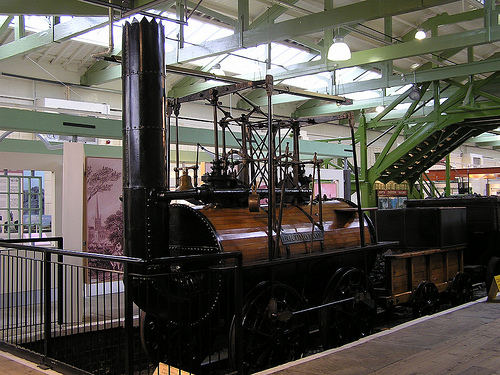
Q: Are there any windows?
A: Yes, there are windows.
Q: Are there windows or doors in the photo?
A: Yes, there are windows.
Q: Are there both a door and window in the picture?
A: No, there are windows but no doors.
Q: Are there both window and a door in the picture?
A: No, there are windows but no doors.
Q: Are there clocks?
A: No, there are no clocks.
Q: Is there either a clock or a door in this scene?
A: No, there are no clocks or doors.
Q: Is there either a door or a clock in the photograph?
A: No, there are no clocks or doors.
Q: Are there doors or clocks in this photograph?
A: No, there are no clocks or doors.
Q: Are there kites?
A: No, there are no kites.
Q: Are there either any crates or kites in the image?
A: No, there are no kites or crates.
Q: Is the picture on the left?
A: Yes, the picture is on the left of the image.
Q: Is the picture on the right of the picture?
A: No, the picture is on the left of the image.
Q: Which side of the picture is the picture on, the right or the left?
A: The picture is on the left of the image.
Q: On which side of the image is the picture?
A: The picture is on the left of the image.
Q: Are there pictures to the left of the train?
A: Yes, there is a picture to the left of the train.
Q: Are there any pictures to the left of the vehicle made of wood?
A: Yes, there is a picture to the left of the train.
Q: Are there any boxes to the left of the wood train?
A: No, there is a picture to the left of the train.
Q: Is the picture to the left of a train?
A: Yes, the picture is to the left of a train.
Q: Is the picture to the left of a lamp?
A: No, the picture is to the left of a train.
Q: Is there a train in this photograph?
A: Yes, there is a train.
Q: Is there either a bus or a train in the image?
A: Yes, there is a train.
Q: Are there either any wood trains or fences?
A: Yes, there is a wood train.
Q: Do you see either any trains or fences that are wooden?
A: Yes, the train is wooden.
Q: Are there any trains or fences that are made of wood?
A: Yes, the train is made of wood.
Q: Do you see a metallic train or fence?
A: Yes, there is a metal train.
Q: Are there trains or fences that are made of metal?
A: Yes, the train is made of metal.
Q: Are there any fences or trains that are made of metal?
A: Yes, the train is made of metal.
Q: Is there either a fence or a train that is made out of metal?
A: Yes, the train is made of metal.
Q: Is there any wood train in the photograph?
A: Yes, there is a wood train.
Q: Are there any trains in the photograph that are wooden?
A: Yes, there is a train that is wooden.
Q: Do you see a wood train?
A: Yes, there is a train that is made of wood.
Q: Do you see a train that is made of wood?
A: Yes, there is a train that is made of wood.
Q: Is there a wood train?
A: Yes, there is a train that is made of wood.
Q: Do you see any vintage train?
A: Yes, there is a vintage train.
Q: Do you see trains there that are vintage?
A: Yes, there is a train that is vintage.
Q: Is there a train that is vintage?
A: Yes, there is a train that is vintage.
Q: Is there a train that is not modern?
A: Yes, there is a vintage train.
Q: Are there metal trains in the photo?
A: Yes, there is a metal train.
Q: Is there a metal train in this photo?
A: Yes, there is a metal train.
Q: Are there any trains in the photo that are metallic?
A: Yes, there is a train that is metallic.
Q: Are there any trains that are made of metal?
A: Yes, there is a train that is made of metal.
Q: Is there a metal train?
A: Yes, there is a train that is made of metal.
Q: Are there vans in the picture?
A: No, there are no vans.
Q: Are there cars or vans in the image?
A: No, there are no vans or cars.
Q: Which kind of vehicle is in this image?
A: The vehicle is a train.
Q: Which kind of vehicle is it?
A: The vehicle is a train.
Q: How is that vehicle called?
A: This is a train.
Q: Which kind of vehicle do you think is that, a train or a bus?
A: This is a train.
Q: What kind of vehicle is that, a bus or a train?
A: This is a train.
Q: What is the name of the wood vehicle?
A: The vehicle is a train.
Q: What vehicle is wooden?
A: The vehicle is a train.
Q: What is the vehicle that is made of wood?
A: The vehicle is a train.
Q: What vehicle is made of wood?
A: The vehicle is a train.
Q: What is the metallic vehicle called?
A: The vehicle is a train.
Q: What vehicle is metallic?
A: The vehicle is a train.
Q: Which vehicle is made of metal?
A: The vehicle is a train.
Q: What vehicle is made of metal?
A: The vehicle is a train.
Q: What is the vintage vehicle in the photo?
A: The vehicle is a train.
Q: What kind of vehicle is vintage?
A: The vehicle is a train.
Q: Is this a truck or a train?
A: This is a train.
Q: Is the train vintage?
A: Yes, the train is vintage.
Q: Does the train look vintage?
A: Yes, the train is vintage.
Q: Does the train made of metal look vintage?
A: Yes, the train is vintage.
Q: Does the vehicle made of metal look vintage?
A: Yes, the train is vintage.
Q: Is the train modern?
A: No, the train is vintage.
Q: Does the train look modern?
A: No, the train is vintage.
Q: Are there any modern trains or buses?
A: No, there is a train but it is vintage.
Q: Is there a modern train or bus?
A: No, there is a train but it is vintage.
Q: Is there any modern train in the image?
A: No, there is a train but it is vintage.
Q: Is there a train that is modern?
A: No, there is a train but it is vintage.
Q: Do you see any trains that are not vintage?
A: No, there is a train but it is vintage.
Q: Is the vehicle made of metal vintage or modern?
A: The train is vintage.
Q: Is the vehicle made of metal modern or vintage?
A: The train is vintage.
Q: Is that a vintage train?
A: Yes, that is a vintage train.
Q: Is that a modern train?
A: No, that is a vintage train.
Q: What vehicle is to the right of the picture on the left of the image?
A: The vehicle is a train.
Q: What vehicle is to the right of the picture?
A: The vehicle is a train.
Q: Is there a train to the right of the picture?
A: Yes, there is a train to the right of the picture.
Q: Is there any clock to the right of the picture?
A: No, there is a train to the right of the picture.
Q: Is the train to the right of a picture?
A: Yes, the train is to the right of a picture.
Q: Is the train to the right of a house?
A: No, the train is to the right of a picture.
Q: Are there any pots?
A: No, there are no pots.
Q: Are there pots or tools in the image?
A: No, there are no pots or tools.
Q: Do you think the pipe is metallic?
A: Yes, the pipe is metallic.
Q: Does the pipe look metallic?
A: Yes, the pipe is metallic.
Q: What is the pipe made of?
A: The pipe is made of metal.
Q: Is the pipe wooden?
A: No, the pipe is metallic.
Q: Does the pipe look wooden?
A: No, the pipe is metallic.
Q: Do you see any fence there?
A: Yes, there is a fence.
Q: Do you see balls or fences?
A: Yes, there is a fence.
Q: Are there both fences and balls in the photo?
A: No, there is a fence but no balls.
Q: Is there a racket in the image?
A: No, there are no rackets.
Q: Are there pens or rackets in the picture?
A: No, there are no rackets or pens.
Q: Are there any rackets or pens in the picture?
A: No, there are no rackets or pens.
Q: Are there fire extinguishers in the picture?
A: No, there are no fire extinguishers.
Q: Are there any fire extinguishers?
A: No, there are no fire extinguishers.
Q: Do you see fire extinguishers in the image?
A: No, there are no fire extinguishers.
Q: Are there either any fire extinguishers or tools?
A: No, there are no fire extinguishers or tools.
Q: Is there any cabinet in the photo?
A: No, there are no cabinets.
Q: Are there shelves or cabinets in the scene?
A: No, there are no cabinets or shelves.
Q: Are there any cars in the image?
A: No, there are no cars.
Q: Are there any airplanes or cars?
A: No, there are no cars or airplanes.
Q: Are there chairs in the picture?
A: No, there are no chairs.